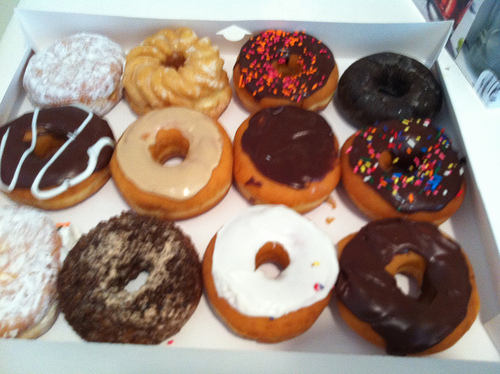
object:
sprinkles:
[429, 178, 442, 192]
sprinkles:
[430, 157, 442, 167]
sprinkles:
[392, 179, 406, 193]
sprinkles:
[404, 129, 427, 145]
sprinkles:
[354, 155, 371, 171]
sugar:
[0, 201, 68, 343]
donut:
[232, 104, 345, 215]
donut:
[202, 202, 340, 346]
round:
[60, 207, 201, 342]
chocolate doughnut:
[52, 210, 207, 346]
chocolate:
[394, 314, 425, 343]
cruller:
[114, 23, 239, 123]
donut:
[18, 31, 129, 113]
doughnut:
[332, 214, 480, 355]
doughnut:
[0, 105, 116, 210]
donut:
[337, 122, 473, 223]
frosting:
[330, 214, 473, 358]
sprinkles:
[373, 129, 385, 137]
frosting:
[236, 101, 339, 190]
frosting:
[0, 101, 120, 197]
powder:
[0, 205, 61, 335]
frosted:
[208, 201, 345, 322]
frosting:
[110, 102, 227, 201]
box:
[0, 2, 500, 374]